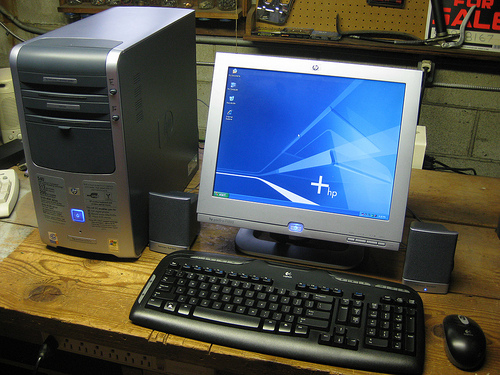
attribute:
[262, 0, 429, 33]
board — brown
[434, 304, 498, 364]
mouse — oval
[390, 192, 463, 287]
speaker. — small, grey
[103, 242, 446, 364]
keyboard — black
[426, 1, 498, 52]
sign — red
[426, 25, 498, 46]
numbers — hand-written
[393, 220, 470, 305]
speaker — gray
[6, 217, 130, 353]
table — wood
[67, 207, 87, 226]
logo — blue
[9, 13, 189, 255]
cpu — silver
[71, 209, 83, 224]
light — blue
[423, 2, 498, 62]
sign — black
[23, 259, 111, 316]
table — tan, wooden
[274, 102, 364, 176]
screen — blue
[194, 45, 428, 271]
screen — grey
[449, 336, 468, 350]
spot — shiny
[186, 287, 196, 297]
key — black